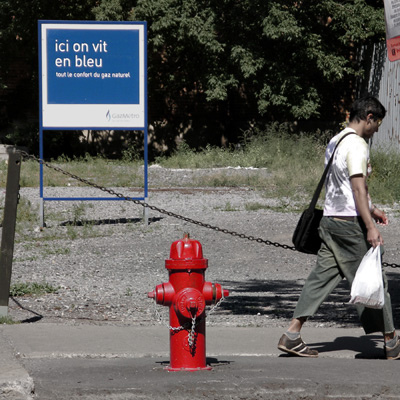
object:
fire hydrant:
[149, 230, 229, 369]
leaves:
[204, 74, 229, 103]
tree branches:
[308, 35, 355, 85]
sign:
[37, 21, 148, 131]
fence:
[0, 140, 400, 319]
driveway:
[0, 185, 400, 328]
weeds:
[66, 200, 90, 241]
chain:
[24, 147, 400, 276]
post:
[0, 150, 22, 306]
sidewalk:
[2, 321, 400, 356]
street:
[25, 357, 399, 399]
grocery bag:
[347, 243, 386, 309]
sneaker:
[278, 332, 318, 358]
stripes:
[290, 341, 303, 348]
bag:
[291, 206, 322, 255]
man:
[277, 97, 400, 358]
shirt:
[324, 125, 371, 216]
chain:
[186, 315, 196, 346]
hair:
[347, 95, 387, 121]